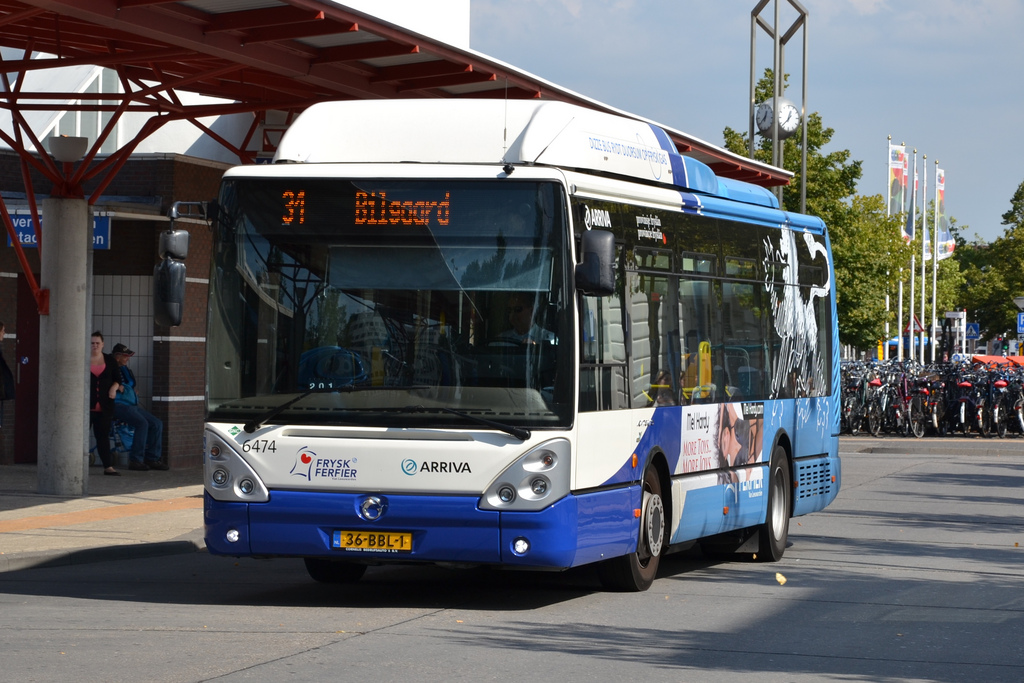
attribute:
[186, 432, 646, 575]
trim — dark, blue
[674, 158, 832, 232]
trim — light-blue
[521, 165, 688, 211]
trim — white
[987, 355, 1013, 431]
motorcycle — parked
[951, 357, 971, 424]
motorcycle — parked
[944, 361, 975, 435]
motorcycle — parked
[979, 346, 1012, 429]
motorcycle — parked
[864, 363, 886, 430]
motorcycle — parked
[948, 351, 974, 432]
motorcycle — parked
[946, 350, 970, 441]
motorcycle — parked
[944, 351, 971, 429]
motorcycle — parked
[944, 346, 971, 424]
motorcycle — parked